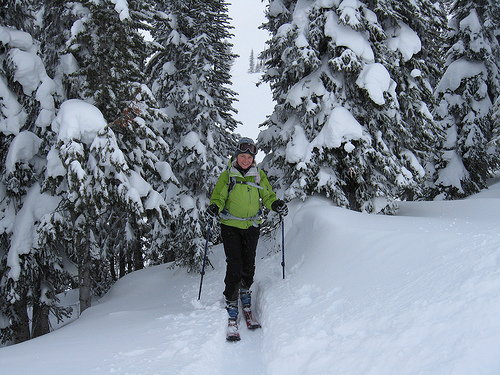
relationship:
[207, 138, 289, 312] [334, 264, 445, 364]
woman standing in snow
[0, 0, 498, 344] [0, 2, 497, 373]
trees with snow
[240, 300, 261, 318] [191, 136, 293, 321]
foot of smiling skier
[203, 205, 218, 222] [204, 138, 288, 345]
hand of smiling skier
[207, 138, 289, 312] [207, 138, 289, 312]
woman dressed in woman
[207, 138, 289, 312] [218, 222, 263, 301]
woman wearing pants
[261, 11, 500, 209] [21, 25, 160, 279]
snow on tree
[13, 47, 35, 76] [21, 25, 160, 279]
snow on tree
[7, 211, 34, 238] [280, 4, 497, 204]
snow on tree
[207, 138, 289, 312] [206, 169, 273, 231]
woman wearing a jacket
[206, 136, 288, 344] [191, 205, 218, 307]
woman carrying pole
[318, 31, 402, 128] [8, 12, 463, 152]
snow on pine trees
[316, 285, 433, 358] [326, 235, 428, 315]
snow on ground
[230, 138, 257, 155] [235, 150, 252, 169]
hat on womans head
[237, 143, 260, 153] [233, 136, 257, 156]
goggles on front of hat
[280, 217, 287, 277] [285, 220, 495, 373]
pole in snow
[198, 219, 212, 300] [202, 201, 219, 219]
pole in glove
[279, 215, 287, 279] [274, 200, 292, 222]
pole in glove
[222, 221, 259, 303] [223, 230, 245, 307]
pants are on leg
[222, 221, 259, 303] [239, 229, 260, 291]
pants are on leg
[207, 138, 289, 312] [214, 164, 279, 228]
woman in coat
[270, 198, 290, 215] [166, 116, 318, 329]
hand of skier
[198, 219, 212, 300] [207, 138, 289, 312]
pole of woman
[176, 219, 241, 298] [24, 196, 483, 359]
pole in snow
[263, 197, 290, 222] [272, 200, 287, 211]
gloves on hand